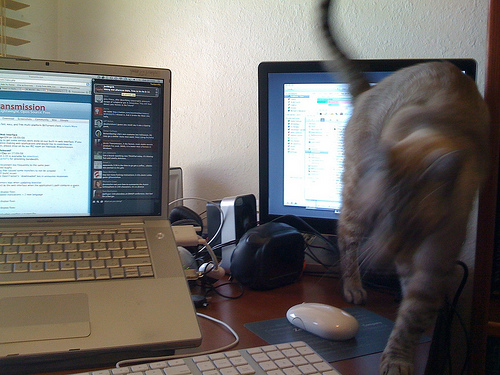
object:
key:
[267, 351, 286, 361]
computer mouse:
[286, 303, 360, 342]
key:
[224, 350, 242, 358]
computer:
[258, 58, 477, 235]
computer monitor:
[258, 58, 478, 236]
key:
[313, 362, 333, 372]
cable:
[197, 239, 218, 270]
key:
[296, 346, 315, 355]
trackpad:
[0, 293, 91, 344]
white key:
[298, 363, 318, 373]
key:
[192, 355, 209, 363]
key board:
[0, 228, 155, 285]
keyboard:
[68, 340, 343, 375]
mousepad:
[244, 306, 433, 362]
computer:
[0, 59, 203, 367]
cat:
[315, 0, 493, 375]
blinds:
[0, 0, 33, 59]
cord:
[115, 312, 240, 367]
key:
[296, 346, 314, 355]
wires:
[168, 197, 225, 254]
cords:
[203, 279, 246, 299]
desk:
[0, 263, 500, 373]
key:
[208, 353, 225, 361]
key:
[281, 348, 300, 358]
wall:
[50, 3, 293, 64]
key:
[251, 353, 270, 363]